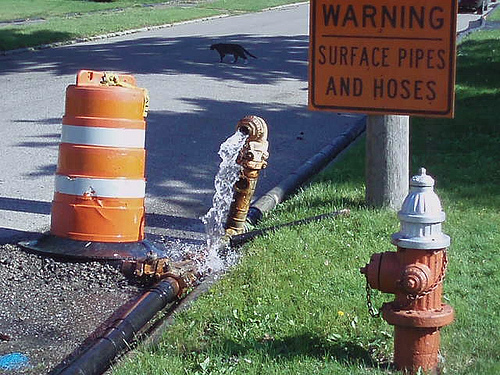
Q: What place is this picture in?
A: It is at the road.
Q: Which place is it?
A: It is a road.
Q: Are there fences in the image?
A: No, there are no fences.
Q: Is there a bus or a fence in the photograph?
A: No, there are no fences or buses.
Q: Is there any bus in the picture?
A: No, there are no buses.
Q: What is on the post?
A: The sign is on the post.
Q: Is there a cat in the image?
A: Yes, there is a cat.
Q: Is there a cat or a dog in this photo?
A: Yes, there is a cat.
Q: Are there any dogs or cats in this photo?
A: Yes, there is a cat.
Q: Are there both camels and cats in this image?
A: No, there is a cat but no camels.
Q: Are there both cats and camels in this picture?
A: No, there is a cat but no camels.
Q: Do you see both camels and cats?
A: No, there is a cat but no camels.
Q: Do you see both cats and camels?
A: No, there is a cat but no camels.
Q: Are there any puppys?
A: No, there are no puppys.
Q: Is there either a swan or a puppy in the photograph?
A: No, there are no puppys or swans.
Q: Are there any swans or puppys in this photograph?
A: No, there are no puppys or swans.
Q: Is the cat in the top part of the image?
A: Yes, the cat is in the top of the image.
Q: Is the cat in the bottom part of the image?
A: No, the cat is in the top of the image.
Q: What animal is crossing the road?
A: The animal is a cat.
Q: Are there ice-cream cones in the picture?
A: No, there are no ice-cream cones.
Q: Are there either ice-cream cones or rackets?
A: No, there are no ice-cream cones or rackets.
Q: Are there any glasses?
A: No, there are no glasses.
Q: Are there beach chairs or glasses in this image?
A: No, there are no glasses or beach chairs.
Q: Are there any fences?
A: No, there are no fences.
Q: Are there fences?
A: No, there are no fences.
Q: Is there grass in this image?
A: Yes, there is grass.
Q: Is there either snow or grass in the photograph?
A: Yes, there is grass.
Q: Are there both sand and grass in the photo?
A: No, there is grass but no sand.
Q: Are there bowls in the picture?
A: No, there are no bowls.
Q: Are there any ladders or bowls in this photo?
A: No, there are no bowls or ladders.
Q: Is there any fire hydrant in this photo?
A: Yes, there is a fire hydrant.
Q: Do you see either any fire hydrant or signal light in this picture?
A: Yes, there is a fire hydrant.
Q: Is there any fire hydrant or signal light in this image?
A: Yes, there is a fire hydrant.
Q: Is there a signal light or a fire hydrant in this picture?
A: Yes, there is a fire hydrant.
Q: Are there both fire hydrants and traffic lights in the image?
A: No, there is a fire hydrant but no traffic lights.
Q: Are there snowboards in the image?
A: No, there are no snowboards.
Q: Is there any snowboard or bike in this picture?
A: No, there are no snowboards or bikes.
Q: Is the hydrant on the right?
A: Yes, the hydrant is on the right of the image.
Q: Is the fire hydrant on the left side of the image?
A: No, the fire hydrant is on the right of the image.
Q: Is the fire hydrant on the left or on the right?
A: The fire hydrant is on the right of the image.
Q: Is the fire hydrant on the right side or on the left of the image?
A: The fire hydrant is on the right of the image.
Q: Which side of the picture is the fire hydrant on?
A: The fire hydrant is on the right of the image.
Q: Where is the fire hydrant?
A: The fire hydrant is in the grass.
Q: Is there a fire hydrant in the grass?
A: Yes, there is a fire hydrant in the grass.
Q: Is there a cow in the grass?
A: No, there is a fire hydrant in the grass.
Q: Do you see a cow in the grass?
A: No, there is a fire hydrant in the grass.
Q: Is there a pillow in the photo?
A: No, there are no pillows.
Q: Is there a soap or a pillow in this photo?
A: No, there are no pillows or soaps.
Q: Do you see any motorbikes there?
A: No, there are no motorbikes.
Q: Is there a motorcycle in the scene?
A: No, there are no motorcycles.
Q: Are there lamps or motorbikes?
A: No, there are no motorbikes or lamps.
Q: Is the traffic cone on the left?
A: Yes, the traffic cone is on the left of the image.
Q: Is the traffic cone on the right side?
A: No, the traffic cone is on the left of the image.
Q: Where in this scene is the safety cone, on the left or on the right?
A: The safety cone is on the left of the image.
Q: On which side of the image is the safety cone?
A: The safety cone is on the left of the image.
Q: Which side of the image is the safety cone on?
A: The safety cone is on the left of the image.